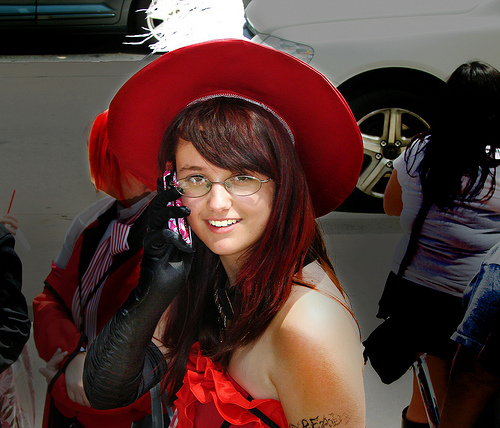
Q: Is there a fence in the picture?
A: No, there are no fences.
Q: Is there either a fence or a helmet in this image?
A: No, there are no fences or helmets.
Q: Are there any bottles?
A: No, there are no bottles.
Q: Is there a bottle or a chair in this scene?
A: No, there are no bottles or chairs.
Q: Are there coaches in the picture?
A: No, there are no coaches.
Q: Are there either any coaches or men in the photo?
A: No, there are no coaches or men.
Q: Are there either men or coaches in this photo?
A: No, there are no coaches or men.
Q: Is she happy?
A: Yes, the girl is happy.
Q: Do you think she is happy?
A: Yes, the girl is happy.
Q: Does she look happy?
A: Yes, the girl is happy.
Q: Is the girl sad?
A: No, the girl is happy.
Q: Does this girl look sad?
A: No, the girl is happy.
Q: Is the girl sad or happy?
A: The girl is happy.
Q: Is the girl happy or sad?
A: The girl is happy.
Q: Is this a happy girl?
A: Yes, this is a happy girl.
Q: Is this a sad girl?
A: No, this is a happy girl.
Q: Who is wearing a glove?
A: The girl is wearing a glove.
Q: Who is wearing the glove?
A: The girl is wearing a glove.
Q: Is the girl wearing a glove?
A: Yes, the girl is wearing a glove.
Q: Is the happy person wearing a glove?
A: Yes, the girl is wearing a glove.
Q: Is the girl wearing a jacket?
A: No, the girl is wearing a glove.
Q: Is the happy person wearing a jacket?
A: No, the girl is wearing a glove.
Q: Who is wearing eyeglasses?
A: The girl is wearing eyeglasses.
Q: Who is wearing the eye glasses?
A: The girl is wearing eyeglasses.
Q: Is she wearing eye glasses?
A: Yes, the girl is wearing eye glasses.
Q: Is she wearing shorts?
A: No, the girl is wearing eye glasses.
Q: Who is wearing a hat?
A: The girl is wearing a hat.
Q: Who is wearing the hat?
A: The girl is wearing a hat.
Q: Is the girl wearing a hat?
A: Yes, the girl is wearing a hat.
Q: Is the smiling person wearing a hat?
A: Yes, the girl is wearing a hat.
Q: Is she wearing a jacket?
A: No, the girl is wearing a hat.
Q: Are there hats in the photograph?
A: Yes, there is a hat.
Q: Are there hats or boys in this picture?
A: Yes, there is a hat.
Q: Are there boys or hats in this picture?
A: Yes, there is a hat.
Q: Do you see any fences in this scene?
A: No, there are no fences.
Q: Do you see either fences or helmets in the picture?
A: No, there are no fences or helmets.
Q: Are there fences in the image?
A: No, there are no fences.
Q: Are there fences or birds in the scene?
A: No, there are no fences or birds.